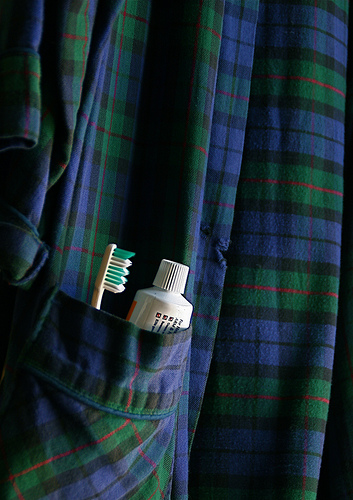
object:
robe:
[2, 4, 345, 492]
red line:
[238, 168, 343, 200]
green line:
[252, 84, 339, 116]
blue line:
[233, 217, 343, 260]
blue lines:
[146, 421, 325, 476]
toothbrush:
[90, 239, 134, 317]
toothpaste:
[130, 255, 199, 333]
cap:
[154, 257, 190, 292]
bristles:
[105, 244, 135, 297]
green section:
[104, 139, 136, 161]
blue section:
[236, 43, 255, 67]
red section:
[239, 174, 273, 189]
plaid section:
[14, 342, 186, 496]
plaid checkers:
[6, 1, 349, 267]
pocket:
[32, 293, 195, 492]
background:
[311, 6, 351, 498]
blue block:
[318, 17, 343, 65]